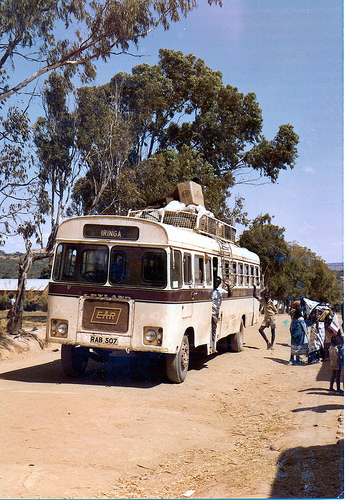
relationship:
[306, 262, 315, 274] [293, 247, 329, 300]
leaves on tree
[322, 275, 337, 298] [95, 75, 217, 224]
leaves on tree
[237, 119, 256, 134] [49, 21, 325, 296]
leaves on tree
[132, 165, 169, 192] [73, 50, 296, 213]
green leaves on tree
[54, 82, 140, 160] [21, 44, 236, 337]
leaves on tree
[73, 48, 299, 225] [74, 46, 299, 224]
leaves on tree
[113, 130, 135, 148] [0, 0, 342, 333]
leaves on tree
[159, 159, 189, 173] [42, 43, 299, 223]
leaves hanging from tree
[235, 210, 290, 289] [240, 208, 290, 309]
leaves on tree